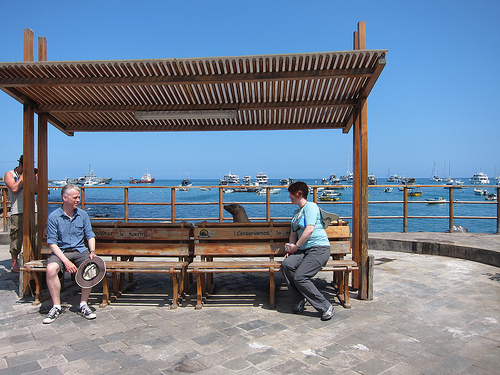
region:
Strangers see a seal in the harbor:
[0, 4, 496, 372]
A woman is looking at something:
[277, 177, 332, 317]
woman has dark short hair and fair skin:
[287, 180, 307, 200]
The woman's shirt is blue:
[292, 202, 322, 247]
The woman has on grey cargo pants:
[280, 245, 327, 320]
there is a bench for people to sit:
[26, 220, 356, 270]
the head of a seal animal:
[217, 200, 247, 221]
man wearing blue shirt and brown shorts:
[45, 182, 95, 317]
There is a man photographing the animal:
[0, 150, 38, 276]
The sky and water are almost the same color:
[366, 40, 492, 232]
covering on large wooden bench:
[41, 53, 381, 143]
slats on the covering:
[186, 73, 299, 124]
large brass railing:
[101, 172, 401, 239]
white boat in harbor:
[134, 167, 164, 182]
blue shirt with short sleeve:
[264, 196, 334, 255]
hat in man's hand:
[74, 252, 122, 304]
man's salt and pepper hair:
[55, 177, 100, 202]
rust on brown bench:
[138, 229, 265, 279]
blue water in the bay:
[106, 191, 224, 213]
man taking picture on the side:
[11, 149, 56, 191]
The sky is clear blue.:
[5, 1, 499, 171]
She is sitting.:
[268, 182, 355, 337]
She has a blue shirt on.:
[284, 205, 324, 242]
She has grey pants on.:
[270, 240, 338, 310]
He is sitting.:
[30, 176, 117, 341]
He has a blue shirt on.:
[45, 200, 109, 270]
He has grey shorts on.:
[36, 235, 96, 272]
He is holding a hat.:
[40, 175, 107, 328]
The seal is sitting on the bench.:
[212, 195, 254, 230]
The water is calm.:
[47, 164, 484, 228]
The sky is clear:
[0, 0, 496, 231]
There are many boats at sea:
[0, 156, 495, 227]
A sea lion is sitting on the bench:
[220, 196, 250, 216]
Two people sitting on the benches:
[40, 180, 335, 320]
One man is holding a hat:
[41, 181, 106, 322]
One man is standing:
[2, 152, 33, 268]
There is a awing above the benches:
[0, 47, 390, 132]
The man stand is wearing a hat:
[1, 150, 36, 270]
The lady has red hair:
[280, 180, 335, 323]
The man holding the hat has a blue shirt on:
[41, 184, 106, 326]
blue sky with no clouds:
[44, 23, 135, 38]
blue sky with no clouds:
[401, 32, 498, 99]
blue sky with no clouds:
[380, 101, 460, 162]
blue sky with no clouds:
[94, 16, 169, 57]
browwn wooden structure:
[55, 68, 313, 122]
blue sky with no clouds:
[152, 142, 229, 169]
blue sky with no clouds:
[205, 139, 313, 167]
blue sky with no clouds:
[61, 142, 121, 167]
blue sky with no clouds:
[272, 13, 354, 47]